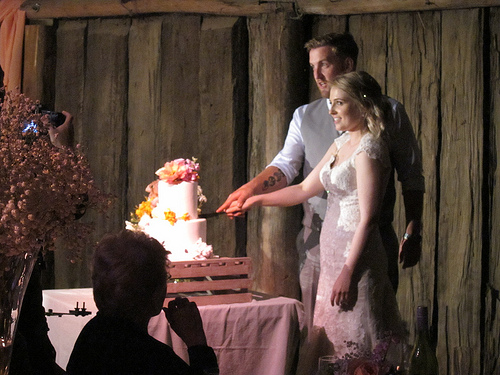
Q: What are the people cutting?
A: Cake.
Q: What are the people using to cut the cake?
A: Knife.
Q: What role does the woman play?
A: Bride.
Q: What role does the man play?
A: Groom.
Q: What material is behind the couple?
A: Wood.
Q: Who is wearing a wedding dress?
A: The woman.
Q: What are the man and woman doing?
A: Cutting a wedding cake.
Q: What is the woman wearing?
A: A wedding dress.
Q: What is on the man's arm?
A: A tattoo.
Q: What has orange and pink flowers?
A: The wedding cake.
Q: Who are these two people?
A: The bride and groom.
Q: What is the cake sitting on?
A: A wooden box.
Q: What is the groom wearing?
A: A vest.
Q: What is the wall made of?
A: Wood.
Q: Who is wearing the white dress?
A: The bride.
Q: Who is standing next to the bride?
A: The groom.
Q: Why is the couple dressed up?
A: It is there wedding.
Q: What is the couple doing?
A: Cutting the cake.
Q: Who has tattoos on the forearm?
A: The groom.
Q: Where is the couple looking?
A: At the camera.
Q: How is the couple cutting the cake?
A: With a knife.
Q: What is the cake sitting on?
A: A crate.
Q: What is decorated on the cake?
A: Flowers.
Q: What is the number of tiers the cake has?
A: Two.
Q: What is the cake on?
A: A crate.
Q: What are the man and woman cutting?
A: A cake.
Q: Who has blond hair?
A: The woman.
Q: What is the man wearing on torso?
A: White shirt.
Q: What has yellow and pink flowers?
A: Cake.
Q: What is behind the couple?
A: Wood wall.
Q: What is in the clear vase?
A: Pink flowers.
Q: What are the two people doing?
A: Cutting a cake.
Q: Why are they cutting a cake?
A: This is a wedding.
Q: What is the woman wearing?
A: A wedding dress.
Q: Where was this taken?
A: At a wedding reception.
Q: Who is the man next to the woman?
A: The groom.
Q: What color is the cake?
A: White.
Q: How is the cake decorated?
A: With flowers.